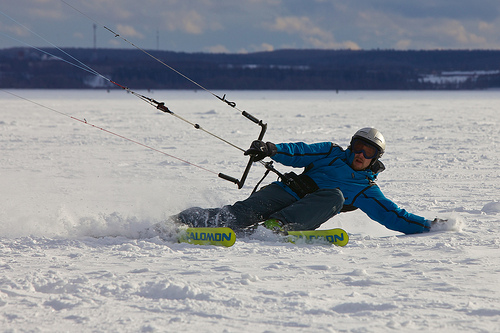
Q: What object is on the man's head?
A: A helmet.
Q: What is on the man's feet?
A: Skis.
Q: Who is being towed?
A: The skier.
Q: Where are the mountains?
A: Behind the field of snow.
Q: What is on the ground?
A: Snow.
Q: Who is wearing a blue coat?
A: The skier.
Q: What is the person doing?
A: Paraskiing.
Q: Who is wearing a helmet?
A: The skier.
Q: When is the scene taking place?
A: Daytime.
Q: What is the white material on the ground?
A: Snow.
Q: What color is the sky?
A: Blue and white.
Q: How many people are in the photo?
A: One.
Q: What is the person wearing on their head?
A: Helmet.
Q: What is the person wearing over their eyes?
A: Goggles.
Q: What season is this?
A: Winter.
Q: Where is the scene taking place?
A: On the snow.